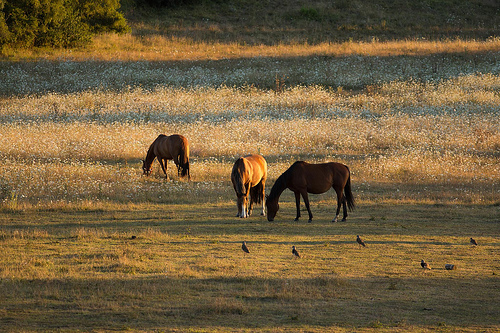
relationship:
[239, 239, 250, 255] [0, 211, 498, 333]
bird in field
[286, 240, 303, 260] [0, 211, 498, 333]
bird in field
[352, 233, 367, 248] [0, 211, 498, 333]
bird in field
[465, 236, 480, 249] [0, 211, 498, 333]
bird in field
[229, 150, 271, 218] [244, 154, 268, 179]
horse has back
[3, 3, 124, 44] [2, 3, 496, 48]
bushes are in background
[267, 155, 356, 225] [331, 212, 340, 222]
horse has hoof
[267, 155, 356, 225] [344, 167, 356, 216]
horse has tail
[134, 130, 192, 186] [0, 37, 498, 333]
horse in field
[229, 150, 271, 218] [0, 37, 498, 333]
horse in field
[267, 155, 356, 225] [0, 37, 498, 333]
horse in field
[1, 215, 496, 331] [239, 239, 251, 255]
grass has bird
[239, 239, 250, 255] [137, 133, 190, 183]
bird near horse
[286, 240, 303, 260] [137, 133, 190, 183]
bird near horse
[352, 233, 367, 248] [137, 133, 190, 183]
bird near horse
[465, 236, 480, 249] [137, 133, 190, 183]
bird near horse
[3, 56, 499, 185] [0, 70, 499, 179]
field has flowers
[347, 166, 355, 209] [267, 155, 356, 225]
tail belongs to horse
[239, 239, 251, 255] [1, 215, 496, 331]
bird are in grass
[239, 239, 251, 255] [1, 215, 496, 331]
bird are on grass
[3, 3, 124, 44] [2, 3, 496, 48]
bush in distance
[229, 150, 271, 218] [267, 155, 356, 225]
horse with another horse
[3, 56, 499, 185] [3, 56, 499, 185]
field has flowers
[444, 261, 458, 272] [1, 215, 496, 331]
item in grass